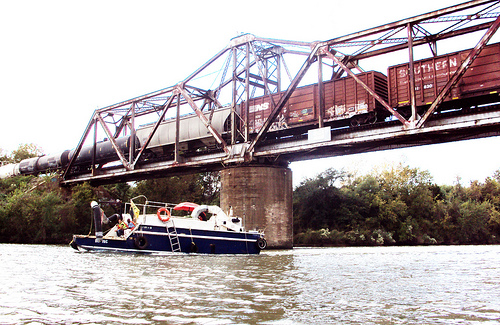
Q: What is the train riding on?
A: A bridge.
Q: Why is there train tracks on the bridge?
A: They are there so the train can cross over the water on the bridge.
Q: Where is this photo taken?
A: Outside on a river.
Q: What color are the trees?
A: Green.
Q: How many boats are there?
A: One.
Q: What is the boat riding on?
A: A river.